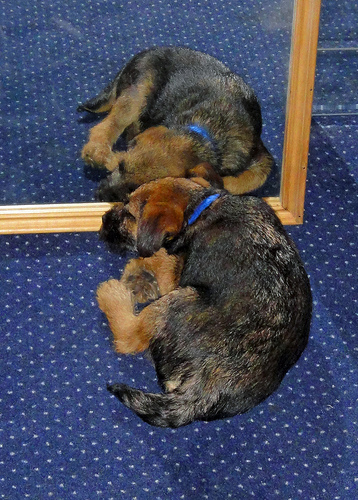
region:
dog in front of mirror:
[107, 197, 310, 438]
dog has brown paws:
[95, 266, 152, 368]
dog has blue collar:
[144, 154, 237, 236]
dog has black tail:
[113, 400, 197, 443]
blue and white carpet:
[21, 350, 105, 486]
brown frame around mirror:
[274, 8, 312, 221]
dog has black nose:
[91, 207, 154, 259]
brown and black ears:
[135, 193, 178, 252]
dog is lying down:
[119, 198, 296, 436]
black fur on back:
[228, 223, 318, 422]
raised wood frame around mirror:
[0, 0, 322, 229]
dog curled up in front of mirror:
[90, 172, 309, 424]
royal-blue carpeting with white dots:
[0, 39, 349, 492]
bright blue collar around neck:
[175, 183, 223, 222]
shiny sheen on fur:
[179, 217, 287, 368]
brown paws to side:
[97, 250, 169, 353]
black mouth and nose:
[92, 200, 114, 245]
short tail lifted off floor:
[71, 79, 111, 122]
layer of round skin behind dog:
[219, 128, 276, 190]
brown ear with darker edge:
[132, 194, 179, 257]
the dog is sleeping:
[99, 155, 293, 451]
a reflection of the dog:
[74, 72, 265, 202]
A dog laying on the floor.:
[92, 178, 317, 427]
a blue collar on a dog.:
[174, 182, 231, 241]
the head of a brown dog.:
[92, 163, 213, 261]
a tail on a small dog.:
[97, 368, 229, 432]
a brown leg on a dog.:
[81, 270, 144, 360]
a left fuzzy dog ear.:
[128, 194, 188, 260]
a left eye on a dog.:
[118, 202, 141, 226]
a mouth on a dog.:
[98, 200, 134, 245]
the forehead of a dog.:
[122, 188, 141, 217]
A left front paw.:
[117, 255, 188, 324]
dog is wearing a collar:
[171, 183, 226, 233]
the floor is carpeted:
[19, 317, 119, 457]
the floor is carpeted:
[38, 359, 167, 498]